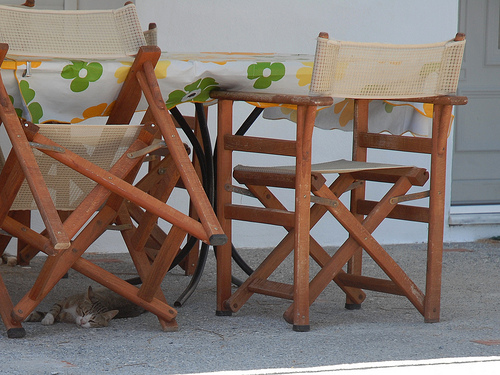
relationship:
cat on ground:
[25, 276, 150, 329] [3, 239, 500, 374]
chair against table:
[2, 3, 225, 336] [1, 54, 453, 309]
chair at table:
[220, 33, 468, 330] [1, 54, 453, 309]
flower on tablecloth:
[246, 61, 285, 90] [2, 52, 454, 126]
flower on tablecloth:
[70, 103, 115, 123] [2, 52, 454, 126]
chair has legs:
[220, 33, 468, 330] [214, 221, 443, 332]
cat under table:
[25, 276, 150, 329] [1, 54, 453, 309]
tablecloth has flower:
[2, 52, 454, 126] [246, 61, 285, 90]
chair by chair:
[2, 3, 225, 336] [220, 33, 468, 330]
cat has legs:
[25, 276, 150, 329] [27, 303, 61, 325]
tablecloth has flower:
[2, 52, 454, 126] [70, 103, 115, 123]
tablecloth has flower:
[2, 52, 454, 126] [167, 78, 220, 107]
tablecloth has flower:
[2, 52, 454, 126] [62, 61, 104, 93]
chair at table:
[2, 3, 225, 336] [1, 54, 453, 309]